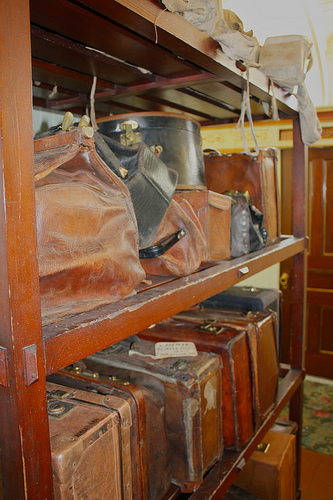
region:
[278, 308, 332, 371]
The brown door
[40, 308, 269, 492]
The suitcases on the middle shelf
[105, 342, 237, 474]
The suitcase is torn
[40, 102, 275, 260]
The bags on the top shelf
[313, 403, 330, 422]
The flower on the rug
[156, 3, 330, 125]
The white bags to the top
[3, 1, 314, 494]
wooden rack lined with very old luggage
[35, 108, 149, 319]
large brown doctor bag with dust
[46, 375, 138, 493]
light brown leather luggage with silver locks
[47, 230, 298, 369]
very dusty wooden shelf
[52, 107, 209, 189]
round black hat box trimmed in brown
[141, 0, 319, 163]
white canvas bags tied with strings on top shelf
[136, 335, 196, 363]
white paper tag with black writing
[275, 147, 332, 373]
wooden door leading to room with brass door knob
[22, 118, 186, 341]
a bag on a shelf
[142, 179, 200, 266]
a bag on a shelf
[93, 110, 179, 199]
a bag on a shelf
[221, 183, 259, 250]
a bag on a shelf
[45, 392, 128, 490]
a suitcase on shelf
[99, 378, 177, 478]
a suitcase on shelf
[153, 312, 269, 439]
a suitcase on shelf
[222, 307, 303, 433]
a suitcase on shelf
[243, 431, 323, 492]
a suitcase on shelf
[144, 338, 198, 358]
A tag on the suitcase.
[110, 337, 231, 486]
The suitcase is old and crappy.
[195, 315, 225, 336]
The lock on the suitcase.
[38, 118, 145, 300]
A bag on the top shelf.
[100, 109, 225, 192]
A hat box on the bag.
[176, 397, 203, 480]
The leather worn off the suitcase.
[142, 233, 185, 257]
The handle is black.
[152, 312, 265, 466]
The suitcase is brown.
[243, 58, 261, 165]
A rope hanging from the bag.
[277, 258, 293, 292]
The knob on the door.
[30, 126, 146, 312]
the luggage is brown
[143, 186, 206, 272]
the luggage is brown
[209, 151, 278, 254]
the luggage is brown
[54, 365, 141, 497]
the luggage is brown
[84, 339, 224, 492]
the luggage is brown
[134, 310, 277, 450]
the luggage is brown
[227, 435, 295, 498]
the luggage is brown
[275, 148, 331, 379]
the door is wood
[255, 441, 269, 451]
the latch is brass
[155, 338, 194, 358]
the tag is paper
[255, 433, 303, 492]
brown briefcase on the shelf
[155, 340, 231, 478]
brown briefcase on the shelf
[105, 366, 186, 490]
brown briefcase on the shelf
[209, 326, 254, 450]
brown briefcase on the shelf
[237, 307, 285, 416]
brown briefcase on the shelf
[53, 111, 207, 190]
the hat box is black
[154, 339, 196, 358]
the tag is white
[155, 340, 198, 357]
the writing on the tag